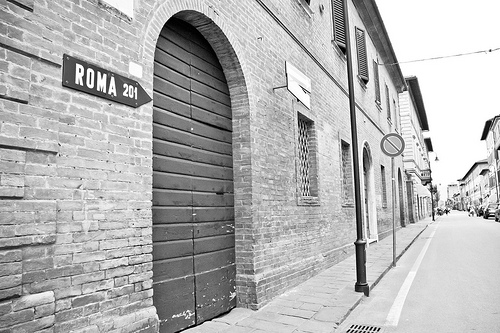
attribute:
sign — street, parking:
[378, 132, 408, 264]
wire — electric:
[399, 46, 499, 66]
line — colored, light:
[395, 260, 415, 315]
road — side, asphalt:
[350, 208, 495, 330]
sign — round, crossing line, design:
[376, 134, 410, 159]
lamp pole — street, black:
[340, 3, 376, 294]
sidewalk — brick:
[179, 214, 437, 331]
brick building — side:
[32, 14, 455, 320]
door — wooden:
[134, 4, 265, 329]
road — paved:
[375, 210, 456, 321]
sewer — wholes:
[346, 321, 387, 331]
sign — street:
[382, 131, 402, 156]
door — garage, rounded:
[149, 19, 237, 331]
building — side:
[2, 0, 406, 331]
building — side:
[69, 5, 382, 312]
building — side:
[125, 9, 405, 255]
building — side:
[78, 15, 396, 238]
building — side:
[54, 52, 316, 260]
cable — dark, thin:
[380, 50, 484, 64]